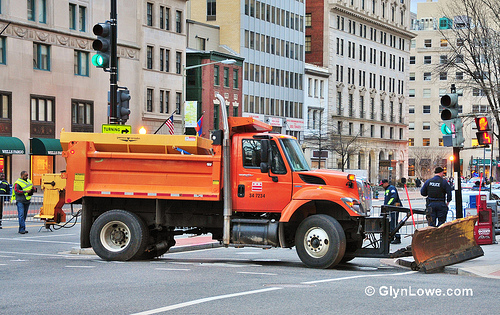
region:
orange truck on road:
[68, 123, 323, 254]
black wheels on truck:
[267, 204, 348, 255]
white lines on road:
[147, 251, 311, 312]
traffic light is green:
[81, 18, 126, 88]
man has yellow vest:
[8, 160, 35, 208]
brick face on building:
[157, 38, 258, 158]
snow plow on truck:
[390, 215, 498, 287]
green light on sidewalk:
[425, 93, 462, 153]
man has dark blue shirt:
[414, 168, 451, 202]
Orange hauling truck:
[36, 90, 484, 275]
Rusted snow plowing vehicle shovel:
[394, 215, 486, 275]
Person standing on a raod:
[7, 168, 38, 235]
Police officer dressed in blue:
[420, 165, 454, 230]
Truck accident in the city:
[0, 1, 497, 312]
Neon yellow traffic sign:
[97, 123, 134, 135]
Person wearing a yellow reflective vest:
[7, 168, 37, 238]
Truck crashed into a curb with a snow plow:
[33, 90, 485, 274]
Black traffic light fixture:
[435, 88, 465, 150]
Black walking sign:
[471, 110, 494, 147]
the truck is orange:
[20, 52, 403, 287]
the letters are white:
[370, 267, 481, 307]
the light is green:
[78, 12, 120, 78]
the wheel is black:
[284, 198, 356, 285]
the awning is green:
[0, 135, 40, 170]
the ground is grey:
[87, 252, 269, 308]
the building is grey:
[220, 5, 313, 122]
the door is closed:
[220, 116, 302, 223]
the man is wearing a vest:
[0, 159, 49, 234]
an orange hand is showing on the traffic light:
[460, 107, 493, 135]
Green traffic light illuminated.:
[87, 21, 119, 72]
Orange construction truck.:
[55, 109, 366, 268]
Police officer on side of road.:
[420, 164, 453, 231]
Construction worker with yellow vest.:
[9, 167, 39, 236]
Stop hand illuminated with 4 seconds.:
[473, 112, 495, 147]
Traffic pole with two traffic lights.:
[90, 0, 131, 139]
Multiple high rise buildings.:
[0, 4, 477, 180]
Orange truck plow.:
[409, 220, 479, 270]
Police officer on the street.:
[376, 174, 405, 249]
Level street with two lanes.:
[5, 240, 436, 313]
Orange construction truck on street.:
[66, 120, 370, 267]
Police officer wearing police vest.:
[419, 161, 451, 240]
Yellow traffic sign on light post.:
[103, 122, 132, 132]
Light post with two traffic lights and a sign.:
[92, 0, 132, 136]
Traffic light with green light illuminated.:
[438, 87, 461, 143]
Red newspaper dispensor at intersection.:
[468, 193, 497, 252]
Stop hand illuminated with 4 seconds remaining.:
[470, 112, 497, 152]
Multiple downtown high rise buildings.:
[0, 2, 492, 178]